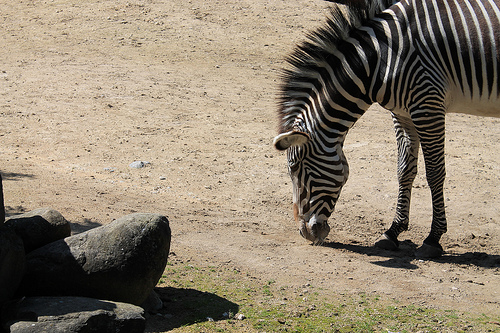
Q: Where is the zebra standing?
A: Dirt.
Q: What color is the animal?
A: Black and white.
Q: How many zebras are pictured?
A: One.